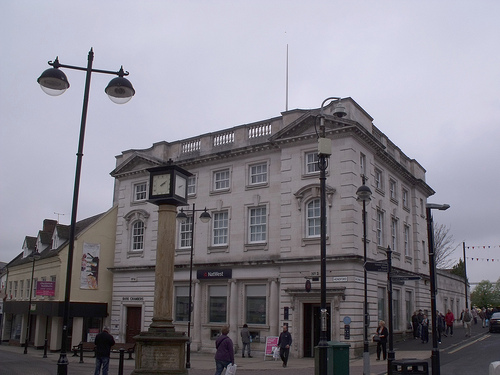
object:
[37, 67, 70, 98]
light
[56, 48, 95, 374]
post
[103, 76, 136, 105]
light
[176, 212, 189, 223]
light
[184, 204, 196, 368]
post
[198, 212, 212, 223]
light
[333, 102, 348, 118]
light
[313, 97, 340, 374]
post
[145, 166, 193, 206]
clock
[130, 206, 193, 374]
tower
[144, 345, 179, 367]
lettering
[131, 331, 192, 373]
base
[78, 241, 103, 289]
banner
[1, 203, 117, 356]
building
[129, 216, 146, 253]
window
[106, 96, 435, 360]
building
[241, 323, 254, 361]
person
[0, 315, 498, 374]
sidewalk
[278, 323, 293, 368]
person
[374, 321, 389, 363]
person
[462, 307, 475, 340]
person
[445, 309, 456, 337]
person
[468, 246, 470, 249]
flag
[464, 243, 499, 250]
line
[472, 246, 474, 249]
flag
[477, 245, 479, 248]
flag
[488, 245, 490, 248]
flag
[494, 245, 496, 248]
flag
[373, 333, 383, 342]
bag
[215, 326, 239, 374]
person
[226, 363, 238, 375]
bag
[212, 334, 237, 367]
jacket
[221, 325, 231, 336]
hair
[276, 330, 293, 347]
jacket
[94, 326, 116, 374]
person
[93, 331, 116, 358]
jacket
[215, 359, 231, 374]
jeans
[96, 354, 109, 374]
jeans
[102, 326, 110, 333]
hair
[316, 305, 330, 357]
door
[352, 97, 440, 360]
side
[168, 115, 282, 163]
railing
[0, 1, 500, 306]
sky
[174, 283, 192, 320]
window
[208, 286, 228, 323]
window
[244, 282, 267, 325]
window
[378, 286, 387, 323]
window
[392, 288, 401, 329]
window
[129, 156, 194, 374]
statue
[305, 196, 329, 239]
window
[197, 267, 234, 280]
logo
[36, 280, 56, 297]
banner